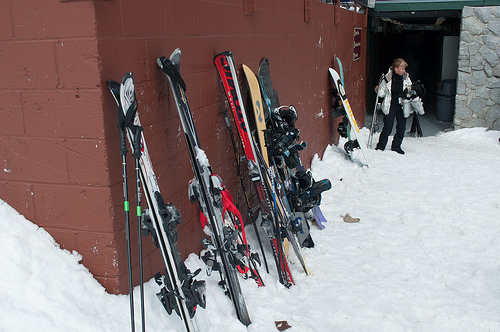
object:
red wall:
[93, 0, 367, 296]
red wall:
[1, 0, 119, 295]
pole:
[367, 73, 385, 149]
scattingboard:
[241, 58, 314, 276]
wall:
[454, 6, 500, 132]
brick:
[52, 38, 149, 90]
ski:
[157, 48, 252, 327]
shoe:
[375, 147, 384, 151]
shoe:
[392, 150, 405, 154]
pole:
[117, 124, 144, 332]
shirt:
[389, 71, 404, 115]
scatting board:
[107, 72, 211, 331]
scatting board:
[156, 47, 251, 327]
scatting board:
[212, 51, 295, 289]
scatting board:
[328, 57, 370, 169]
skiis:
[106, 47, 372, 331]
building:
[0, 1, 499, 295]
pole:
[219, 110, 291, 289]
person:
[374, 58, 425, 155]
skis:
[329, 57, 371, 169]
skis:
[154, 48, 251, 327]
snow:
[0, 128, 499, 332]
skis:
[367, 73, 385, 149]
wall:
[0, 0, 370, 296]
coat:
[374, 65, 426, 118]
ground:
[0, 113, 500, 331]